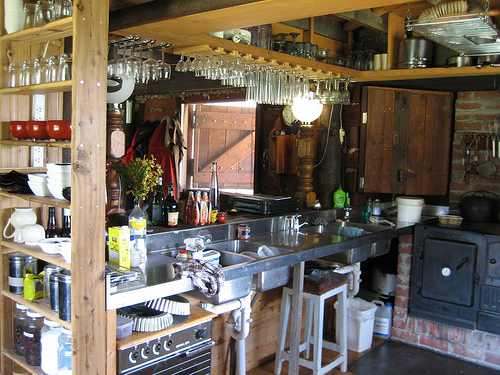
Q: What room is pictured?
A: The kitchen.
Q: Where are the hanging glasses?
A: Above the sink.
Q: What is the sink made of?
A: Stainless steel.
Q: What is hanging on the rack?
A: Wine glasses.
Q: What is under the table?
A: A stool.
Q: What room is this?
A: Kitchen.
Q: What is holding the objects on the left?
A: A shelf.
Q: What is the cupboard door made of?
A: Wood.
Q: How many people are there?
A: None.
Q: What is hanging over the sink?
A: Glasses.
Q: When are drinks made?
A: After they are ordered.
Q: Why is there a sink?
A: Wash glasses.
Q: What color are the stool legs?
A: White.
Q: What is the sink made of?
A: Steel.